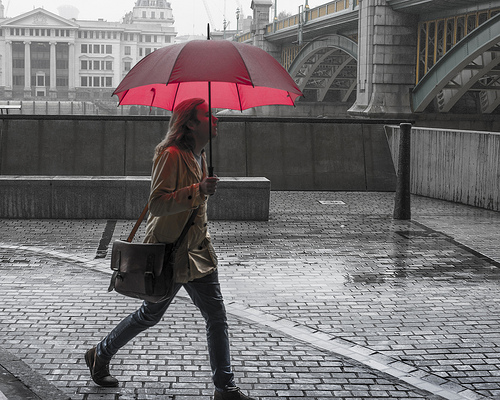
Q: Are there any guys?
A: No, there are no guys.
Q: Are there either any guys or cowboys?
A: No, there are no guys or cowboys.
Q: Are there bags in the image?
A: Yes, there is a bag.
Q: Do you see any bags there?
A: Yes, there is a bag.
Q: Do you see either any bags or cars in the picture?
A: Yes, there is a bag.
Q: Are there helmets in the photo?
A: No, there are no helmets.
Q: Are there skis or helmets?
A: No, there are no helmets or skis.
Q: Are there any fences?
A: No, there are no fences.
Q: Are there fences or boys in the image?
A: No, there are no fences or boys.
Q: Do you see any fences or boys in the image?
A: No, there are no fences or boys.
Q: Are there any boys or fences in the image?
A: No, there are no fences or boys.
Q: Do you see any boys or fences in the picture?
A: No, there are no fences or boys.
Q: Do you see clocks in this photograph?
A: No, there are no clocks.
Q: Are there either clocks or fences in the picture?
A: No, there are no clocks or fences.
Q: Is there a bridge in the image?
A: Yes, there is a bridge.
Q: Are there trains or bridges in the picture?
A: Yes, there is a bridge.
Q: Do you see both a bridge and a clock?
A: No, there is a bridge but no clocks.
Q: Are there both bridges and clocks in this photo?
A: No, there is a bridge but no clocks.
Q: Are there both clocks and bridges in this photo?
A: No, there is a bridge but no clocks.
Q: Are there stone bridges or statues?
A: Yes, there is a stone bridge.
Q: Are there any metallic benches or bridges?
A: Yes, there is a metal bridge.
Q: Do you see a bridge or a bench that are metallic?
A: Yes, the bridge is metallic.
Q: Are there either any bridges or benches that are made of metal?
A: Yes, the bridge is made of metal.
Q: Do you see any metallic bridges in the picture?
A: Yes, there is a metal bridge.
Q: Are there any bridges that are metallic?
A: Yes, there is a bridge that is metallic.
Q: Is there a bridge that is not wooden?
A: Yes, there is a metallic bridge.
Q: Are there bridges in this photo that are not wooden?
A: Yes, there is a metallic bridge.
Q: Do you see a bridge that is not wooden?
A: Yes, there is a metallic bridge.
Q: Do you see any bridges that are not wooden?
A: Yes, there is a metallic bridge.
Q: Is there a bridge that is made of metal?
A: Yes, there is a bridge that is made of metal.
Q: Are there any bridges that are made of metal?
A: Yes, there is a bridge that is made of metal.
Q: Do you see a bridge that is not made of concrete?
A: Yes, there is a bridge that is made of metal.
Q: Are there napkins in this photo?
A: No, there are no napkins.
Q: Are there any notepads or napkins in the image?
A: No, there are no napkins or notepads.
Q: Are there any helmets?
A: No, there are no helmets.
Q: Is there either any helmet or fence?
A: No, there are no helmets or fences.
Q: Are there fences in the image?
A: No, there are no fences.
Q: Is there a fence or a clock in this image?
A: No, there are no fences or clocks.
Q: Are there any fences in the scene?
A: No, there are no fences.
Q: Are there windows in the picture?
A: Yes, there are windows.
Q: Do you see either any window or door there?
A: Yes, there are windows.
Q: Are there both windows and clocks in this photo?
A: No, there are windows but no clocks.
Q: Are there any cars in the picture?
A: No, there are no cars.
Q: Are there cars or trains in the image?
A: No, there are no cars or trains.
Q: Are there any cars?
A: No, there are no cars.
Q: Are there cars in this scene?
A: No, there are no cars.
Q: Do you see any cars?
A: No, there are no cars.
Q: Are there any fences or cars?
A: No, there are no cars or fences.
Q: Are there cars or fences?
A: No, there are no cars or fences.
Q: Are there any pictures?
A: No, there are no pictures.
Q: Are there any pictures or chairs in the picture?
A: No, there are no pictures or chairs.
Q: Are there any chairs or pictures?
A: No, there are no pictures or chairs.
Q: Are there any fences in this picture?
A: No, there are no fences.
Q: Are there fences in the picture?
A: No, there are no fences.